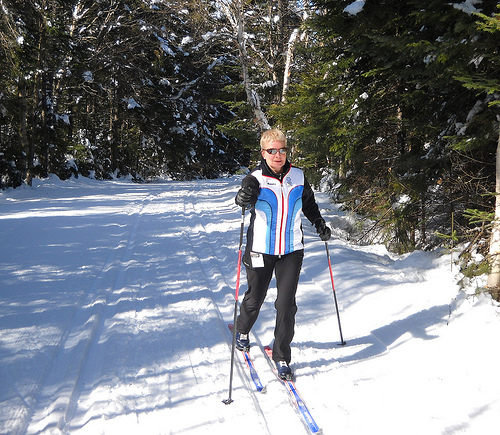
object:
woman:
[231, 124, 335, 382]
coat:
[235, 160, 327, 262]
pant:
[232, 244, 304, 365]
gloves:
[315, 219, 333, 242]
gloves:
[233, 187, 251, 210]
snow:
[1, 174, 499, 435]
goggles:
[261, 146, 289, 156]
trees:
[1, 1, 39, 182]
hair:
[254, 127, 288, 150]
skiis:
[226, 320, 323, 435]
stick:
[321, 232, 351, 345]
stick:
[223, 204, 247, 400]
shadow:
[276, 285, 473, 383]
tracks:
[178, 185, 292, 430]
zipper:
[275, 185, 286, 261]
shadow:
[1, 176, 412, 434]